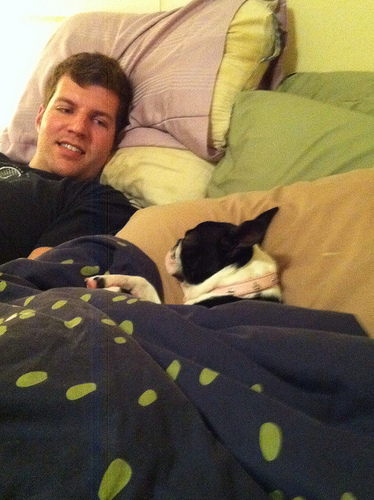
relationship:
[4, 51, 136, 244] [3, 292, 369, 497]
man in bed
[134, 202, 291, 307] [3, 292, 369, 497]
dog in bed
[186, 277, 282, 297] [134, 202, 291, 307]
collar on dog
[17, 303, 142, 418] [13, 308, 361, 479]
designs on blanket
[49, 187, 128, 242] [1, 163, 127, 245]
sleeves of shirt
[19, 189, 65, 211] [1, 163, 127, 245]
black tee shirt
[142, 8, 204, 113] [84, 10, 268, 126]
purple pillow case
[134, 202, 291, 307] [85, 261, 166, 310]
dog has paw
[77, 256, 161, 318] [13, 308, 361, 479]
top of blanket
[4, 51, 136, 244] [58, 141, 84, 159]
man has teeth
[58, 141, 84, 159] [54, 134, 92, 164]
teeth in mouth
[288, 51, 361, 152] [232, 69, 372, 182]
two green pillows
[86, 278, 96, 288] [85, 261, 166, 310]
pad on paw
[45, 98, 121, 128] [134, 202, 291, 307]
looking at dog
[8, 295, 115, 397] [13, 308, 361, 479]
dots on blanket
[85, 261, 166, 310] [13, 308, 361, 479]
paw over blanket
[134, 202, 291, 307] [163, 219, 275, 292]
dog has head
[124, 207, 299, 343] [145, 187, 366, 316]
resting on pillow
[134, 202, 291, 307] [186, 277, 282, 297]
dog wearing collar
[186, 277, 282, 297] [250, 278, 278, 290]
collar has studs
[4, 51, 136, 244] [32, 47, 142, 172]
man's elevated head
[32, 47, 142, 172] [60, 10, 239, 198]
head on pillows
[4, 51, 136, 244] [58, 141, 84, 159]
man showing teeth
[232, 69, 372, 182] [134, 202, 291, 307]
pillows behind dog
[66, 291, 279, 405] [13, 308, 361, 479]
folds across blankets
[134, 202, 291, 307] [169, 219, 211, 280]
dog has face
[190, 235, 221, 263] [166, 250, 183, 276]
black and white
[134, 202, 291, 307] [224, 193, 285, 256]
dog has ears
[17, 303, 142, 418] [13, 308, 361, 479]
spots on blanket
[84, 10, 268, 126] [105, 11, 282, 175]
case covering pillow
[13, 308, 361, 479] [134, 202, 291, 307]
blanket covering dog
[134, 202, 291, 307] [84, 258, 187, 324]
dog has paws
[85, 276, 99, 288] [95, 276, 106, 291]
pink and black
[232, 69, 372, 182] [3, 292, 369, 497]
pillowcase on bed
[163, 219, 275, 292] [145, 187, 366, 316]
head on pillow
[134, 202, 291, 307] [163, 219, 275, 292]
dog's black head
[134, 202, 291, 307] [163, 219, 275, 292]
dog's white head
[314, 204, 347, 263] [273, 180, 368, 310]
tan pillow case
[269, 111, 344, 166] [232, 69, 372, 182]
green pillow cases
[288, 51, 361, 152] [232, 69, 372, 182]
two green cases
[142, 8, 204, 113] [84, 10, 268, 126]
lavender pillow case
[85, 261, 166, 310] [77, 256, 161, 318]
paw on top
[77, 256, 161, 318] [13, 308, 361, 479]
top of bedspread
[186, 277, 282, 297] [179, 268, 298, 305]
collar on neck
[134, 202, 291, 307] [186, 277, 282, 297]
dog has collar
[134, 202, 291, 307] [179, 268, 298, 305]
dog has neck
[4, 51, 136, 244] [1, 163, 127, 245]
man in t-shirt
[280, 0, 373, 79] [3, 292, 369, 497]
wall behind bed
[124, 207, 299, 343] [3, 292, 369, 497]
laying under covers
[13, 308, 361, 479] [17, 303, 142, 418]
blanket with spots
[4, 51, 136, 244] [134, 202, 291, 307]
man beside dog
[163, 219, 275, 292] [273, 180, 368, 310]
head on pillowcase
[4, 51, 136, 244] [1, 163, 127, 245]
man wearing shirt